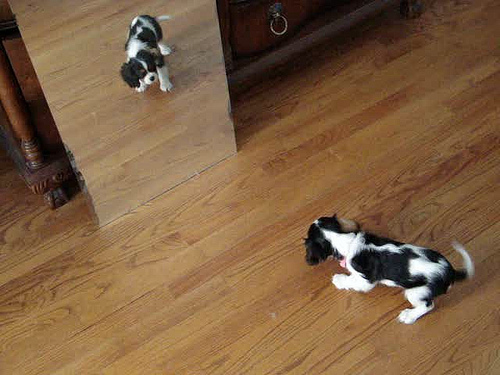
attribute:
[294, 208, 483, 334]
puppy — black, white, brown, partially black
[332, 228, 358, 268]
collar — pink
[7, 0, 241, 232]
mirror — unframed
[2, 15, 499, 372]
floor — wooden, partially visible, brown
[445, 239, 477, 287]
tail — white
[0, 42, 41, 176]
post — polished